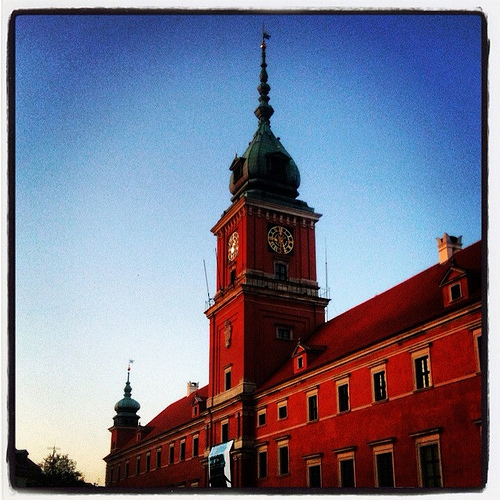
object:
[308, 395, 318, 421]
window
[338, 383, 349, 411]
window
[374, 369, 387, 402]
window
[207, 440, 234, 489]
banner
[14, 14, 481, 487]
blue sky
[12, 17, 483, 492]
clear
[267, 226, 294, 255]
clock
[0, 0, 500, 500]
photograph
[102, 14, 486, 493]
building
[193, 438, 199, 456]
windows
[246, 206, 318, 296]
wall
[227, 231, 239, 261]
clocks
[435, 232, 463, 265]
chimney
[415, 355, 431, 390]
window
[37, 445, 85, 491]
green trees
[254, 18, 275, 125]
turret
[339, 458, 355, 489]
window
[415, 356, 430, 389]
courtain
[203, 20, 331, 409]
tower